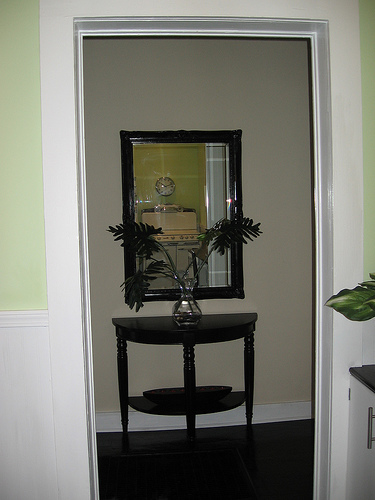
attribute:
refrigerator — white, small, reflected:
[142, 204, 200, 289]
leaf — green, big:
[323, 273, 374, 322]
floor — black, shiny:
[98, 419, 316, 498]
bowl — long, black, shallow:
[142, 388, 230, 403]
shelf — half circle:
[128, 393, 246, 414]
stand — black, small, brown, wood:
[113, 313, 255, 451]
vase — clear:
[168, 271, 201, 329]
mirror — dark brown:
[121, 128, 241, 301]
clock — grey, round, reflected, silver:
[155, 177, 175, 196]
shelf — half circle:
[112, 312, 256, 344]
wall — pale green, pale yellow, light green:
[1, 0, 48, 312]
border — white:
[1, 310, 57, 499]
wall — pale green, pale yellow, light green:
[359, 1, 374, 278]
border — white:
[357, 317, 374, 366]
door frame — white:
[40, 1, 363, 499]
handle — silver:
[367, 408, 374, 450]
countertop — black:
[350, 366, 374, 392]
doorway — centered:
[82, 34, 310, 500]